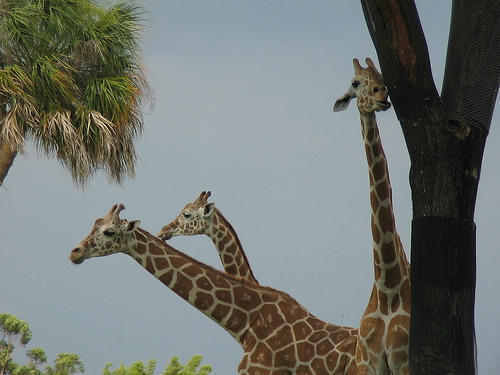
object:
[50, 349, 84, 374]
leaves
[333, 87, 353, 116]
ear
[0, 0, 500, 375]
sky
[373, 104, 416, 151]
ground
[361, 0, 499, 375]
tree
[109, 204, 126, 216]
ossicones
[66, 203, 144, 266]
head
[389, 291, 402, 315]
brown spot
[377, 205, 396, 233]
brown spot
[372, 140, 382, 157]
brown spot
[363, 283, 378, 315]
brown spot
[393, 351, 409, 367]
brown spot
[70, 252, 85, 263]
giraffe mouth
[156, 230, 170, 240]
giraffe mouth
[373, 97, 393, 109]
giraffe mouth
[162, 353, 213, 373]
leaves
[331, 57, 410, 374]
giraffe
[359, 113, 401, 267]
neck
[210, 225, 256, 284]
neck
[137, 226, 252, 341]
neck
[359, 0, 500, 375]
trunk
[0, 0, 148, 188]
leaves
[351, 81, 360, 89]
eye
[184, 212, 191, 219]
eye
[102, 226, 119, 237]
eye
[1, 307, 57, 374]
leaves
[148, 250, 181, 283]
spots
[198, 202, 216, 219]
ear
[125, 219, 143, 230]
ear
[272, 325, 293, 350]
spots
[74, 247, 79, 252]
nostrils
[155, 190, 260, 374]
giraffe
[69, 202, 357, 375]
giraffe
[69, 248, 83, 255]
brown nose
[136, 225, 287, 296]
mane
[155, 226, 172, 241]
nose